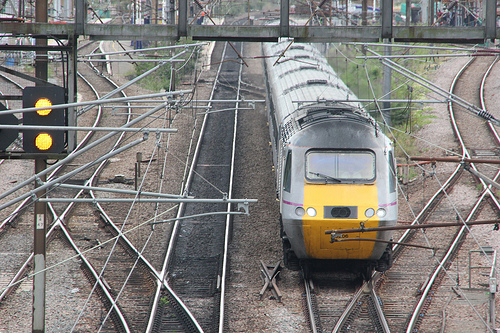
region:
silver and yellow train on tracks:
[241, 28, 414, 292]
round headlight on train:
[289, 203, 305, 220]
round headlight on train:
[306, 203, 316, 223]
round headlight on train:
[364, 207, 373, 220]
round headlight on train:
[375, 206, 384, 221]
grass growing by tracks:
[142, 48, 194, 96]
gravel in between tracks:
[236, 219, 261, 249]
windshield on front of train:
[311, 146, 373, 178]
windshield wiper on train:
[306, 165, 341, 185]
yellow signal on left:
[13, 69, 77, 156]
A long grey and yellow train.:
[260, 19, 402, 279]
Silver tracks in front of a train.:
[297, 264, 389, 332]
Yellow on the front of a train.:
[306, 182, 378, 261]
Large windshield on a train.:
[305, 145, 375, 184]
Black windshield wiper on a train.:
[308, 168, 341, 188]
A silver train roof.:
[266, 14, 389, 145]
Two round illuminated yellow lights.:
[34, 99, 52, 151]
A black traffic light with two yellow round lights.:
[21, 84, 68, 156]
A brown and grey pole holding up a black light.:
[33, 155, 46, 331]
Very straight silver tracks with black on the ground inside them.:
[141, 19, 249, 332]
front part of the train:
[281, 103, 403, 261]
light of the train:
[280, 181, 338, 233]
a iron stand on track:
[246, 251, 297, 308]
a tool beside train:
[236, 236, 284, 311]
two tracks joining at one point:
[85, 273, 227, 331]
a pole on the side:
[315, 220, 495, 242]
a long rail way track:
[161, 44, 263, 326]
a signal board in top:
[7, 78, 73, 163]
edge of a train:
[294, 180, 322, 209]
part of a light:
[38, 172, 50, 185]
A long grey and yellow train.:
[258, 22, 398, 274]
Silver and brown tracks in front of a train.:
[297, 266, 392, 332]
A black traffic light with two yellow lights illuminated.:
[19, 88, 64, 153]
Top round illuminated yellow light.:
[33, 99, 50, 117]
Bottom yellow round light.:
[34, 134, 52, 150]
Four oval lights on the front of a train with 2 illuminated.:
[292, 204, 386, 219]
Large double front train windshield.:
[303, 149, 378, 181]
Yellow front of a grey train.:
[301, 181, 378, 263]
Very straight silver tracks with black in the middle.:
[151, 42, 241, 332]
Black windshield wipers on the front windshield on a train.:
[306, 171, 340, 186]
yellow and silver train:
[261, 40, 398, 278]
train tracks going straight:
[144, 42, 246, 332]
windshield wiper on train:
[307, 170, 343, 185]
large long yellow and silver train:
[263, 31, 398, 271]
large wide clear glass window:
[305, 144, 378, 180]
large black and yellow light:
[19, 85, 70, 157]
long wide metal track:
[141, 39, 250, 331]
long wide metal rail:
[0, 0, 499, 49]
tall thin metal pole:
[34, 157, 49, 332]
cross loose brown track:
[256, 259, 286, 299]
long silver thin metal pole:
[36, 192, 258, 204]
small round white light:
[306, 205, 318, 217]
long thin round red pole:
[394, 156, 499, 170]